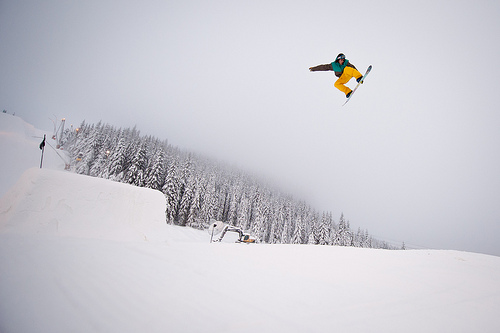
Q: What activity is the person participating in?
A: Snowboarding.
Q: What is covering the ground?
A: Snow.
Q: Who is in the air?
A: Snowboarder.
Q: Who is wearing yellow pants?
A: Snowboarder.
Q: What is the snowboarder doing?
A: Jumping.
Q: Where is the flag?
A: Behind the ramp.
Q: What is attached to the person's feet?
A: A snowboard.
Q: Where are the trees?
A: Behind the slope.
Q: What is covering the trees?
A: Snow.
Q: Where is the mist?
A: Just over the trees.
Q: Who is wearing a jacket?
A: Snowboarder.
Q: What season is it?
A: Winter.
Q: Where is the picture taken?
A: Ski slope.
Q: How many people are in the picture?
A: One.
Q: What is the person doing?
A: Snowboarding.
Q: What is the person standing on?
A: A snowboard.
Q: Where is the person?
A: The air.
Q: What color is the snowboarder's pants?
A: Yellow.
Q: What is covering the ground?
A: Snow.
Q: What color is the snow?
A: White.